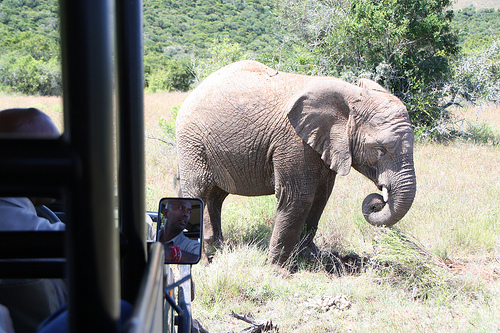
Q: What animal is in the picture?
A: An elephant.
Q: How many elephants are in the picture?
A: One.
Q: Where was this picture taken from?
A: A vehicle.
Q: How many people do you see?
A: One.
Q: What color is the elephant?
A: Gray.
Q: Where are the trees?
A: Behind the elephant.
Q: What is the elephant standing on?
A: Grass.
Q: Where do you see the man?
A: In the mirror.